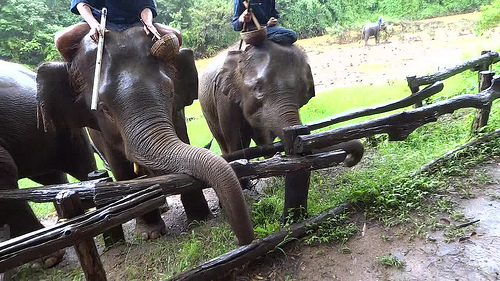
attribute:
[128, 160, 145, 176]
tusk — small